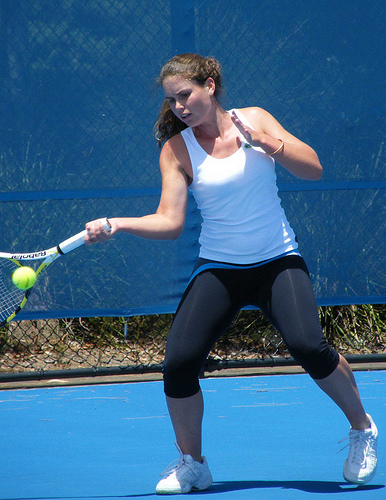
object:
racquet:
[0, 215, 113, 330]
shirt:
[177, 105, 301, 263]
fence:
[2, 2, 383, 346]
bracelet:
[263, 138, 287, 164]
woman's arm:
[256, 104, 322, 187]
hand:
[85, 216, 118, 247]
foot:
[153, 445, 216, 498]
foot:
[337, 414, 378, 486]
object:
[9, 4, 377, 311]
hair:
[157, 51, 224, 141]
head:
[158, 54, 222, 130]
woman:
[84, 52, 380, 495]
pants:
[162, 255, 337, 400]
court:
[8, 331, 372, 495]